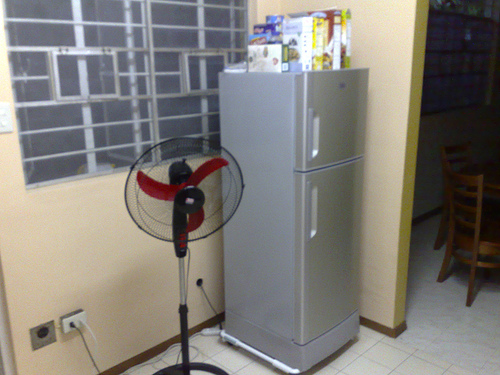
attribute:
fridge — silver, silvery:
[217, 65, 364, 364]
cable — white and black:
[52, 297, 129, 359]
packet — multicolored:
[245, 41, 291, 74]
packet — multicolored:
[281, 18, 311, 71]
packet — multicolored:
[308, 12, 324, 70]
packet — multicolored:
[282, 9, 342, 68]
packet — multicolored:
[243, 31, 283, 46]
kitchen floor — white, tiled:
[356, 334, 393, 369]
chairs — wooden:
[436, 139, 498, 317]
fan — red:
[130, 149, 231, 234]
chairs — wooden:
[429, 139, 499, 309]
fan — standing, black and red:
[123, 137, 246, 372]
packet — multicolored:
[311, 9, 375, 76]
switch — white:
[0, 98, 40, 169]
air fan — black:
[121, 137, 258, 264]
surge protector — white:
[198, 324, 223, 338]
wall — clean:
[1, 0, 281, 372]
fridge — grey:
[203, 27, 413, 370]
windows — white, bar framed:
[5, 0, 242, 175]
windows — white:
[4, 3, 252, 183]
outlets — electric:
[26, 306, 87, 345]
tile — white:
[363, 334, 407, 370]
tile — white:
[392, 355, 444, 370]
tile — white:
[209, 346, 251, 373]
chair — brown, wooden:
[436, 167, 498, 309]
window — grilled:
[3, 0, 261, 188]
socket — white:
[62, 307, 87, 338]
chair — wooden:
[429, 136, 472, 256]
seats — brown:
[438, 136, 492, 316]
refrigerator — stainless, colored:
[215, 63, 370, 373]